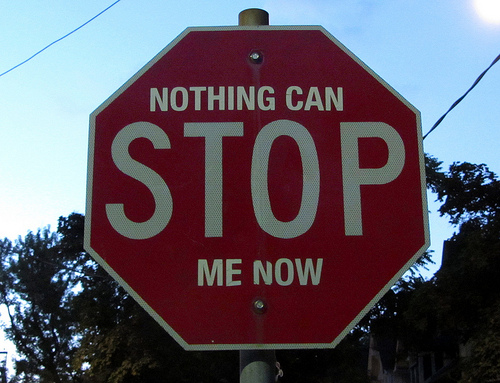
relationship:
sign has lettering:
[84, 22, 430, 353] [109, 83, 405, 286]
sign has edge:
[84, 22, 430, 353] [189, 25, 322, 33]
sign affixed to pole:
[84, 22, 430, 353] [238, 8, 278, 382]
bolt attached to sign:
[248, 50, 262, 63] [84, 22, 430, 353]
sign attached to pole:
[84, 22, 430, 353] [238, 8, 278, 382]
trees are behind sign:
[0, 156, 496, 382] [84, 22, 430, 353]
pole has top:
[238, 8, 278, 382] [238, 7, 270, 26]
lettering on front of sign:
[109, 83, 405, 286] [84, 22, 430, 353]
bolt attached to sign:
[254, 300, 270, 315] [84, 22, 430, 353]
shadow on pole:
[237, 351, 284, 374] [238, 8, 278, 382]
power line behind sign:
[0, 1, 125, 87] [84, 22, 430, 353]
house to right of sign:
[363, 238, 489, 377] [84, 22, 430, 353]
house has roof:
[363, 238, 489, 377] [370, 315, 464, 350]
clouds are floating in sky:
[3, 182, 81, 238] [1, 2, 498, 286]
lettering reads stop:
[109, 83, 405, 286] [105, 122, 408, 236]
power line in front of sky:
[0, 1, 125, 87] [1, 2, 498, 286]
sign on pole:
[84, 22, 430, 353] [238, 8, 278, 382]